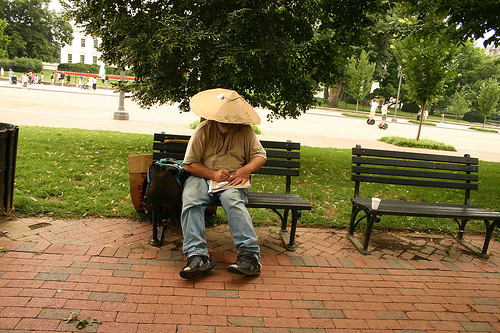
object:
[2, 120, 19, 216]
can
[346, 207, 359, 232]
bench legs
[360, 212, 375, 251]
bench legs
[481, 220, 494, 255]
bench legs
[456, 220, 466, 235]
bench legs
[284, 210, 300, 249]
bench legs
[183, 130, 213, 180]
arm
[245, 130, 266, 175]
arm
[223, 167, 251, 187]
hand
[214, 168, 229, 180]
hand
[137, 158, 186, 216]
bag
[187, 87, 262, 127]
hat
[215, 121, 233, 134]
head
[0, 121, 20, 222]
trash can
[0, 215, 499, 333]
pathway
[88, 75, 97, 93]
people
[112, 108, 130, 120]
bottom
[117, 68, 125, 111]
pole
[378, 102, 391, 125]
people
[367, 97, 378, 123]
people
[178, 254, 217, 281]
shoes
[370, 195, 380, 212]
cup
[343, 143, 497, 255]
bench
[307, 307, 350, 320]
bricks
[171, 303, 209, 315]
bricks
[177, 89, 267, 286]
man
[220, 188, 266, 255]
leg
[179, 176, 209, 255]
leg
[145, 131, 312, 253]
bench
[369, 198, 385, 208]
coffee cup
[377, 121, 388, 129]
segways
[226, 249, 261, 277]
sandals